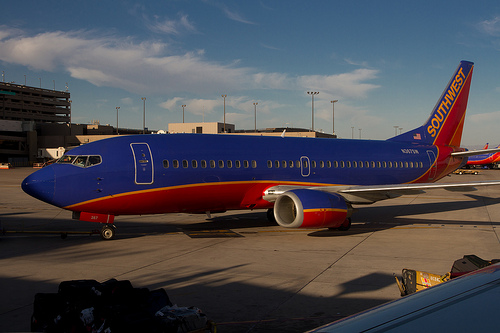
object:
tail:
[424, 60, 475, 141]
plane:
[20, 59, 499, 239]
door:
[130, 141, 155, 186]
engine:
[271, 186, 349, 230]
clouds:
[0, 17, 388, 116]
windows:
[160, 158, 257, 169]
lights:
[113, 90, 338, 110]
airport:
[0, 145, 499, 332]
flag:
[412, 132, 422, 140]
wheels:
[99, 225, 119, 241]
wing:
[261, 180, 499, 211]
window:
[159, 160, 169, 167]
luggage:
[33, 275, 217, 332]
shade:
[188, 281, 362, 317]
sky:
[30, 22, 500, 113]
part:
[136, 151, 149, 167]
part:
[3, 171, 22, 182]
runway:
[0, 195, 498, 252]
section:
[267, 162, 269, 168]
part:
[182, 68, 225, 87]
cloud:
[322, 71, 374, 100]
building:
[113, 121, 338, 139]